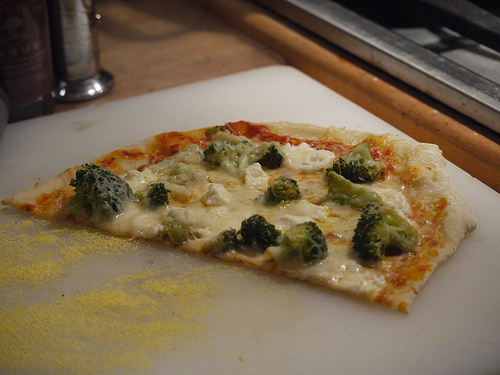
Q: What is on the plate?
A: Yellow seasonings.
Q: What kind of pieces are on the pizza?
A: Broccoli.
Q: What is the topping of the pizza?
A: Cheese.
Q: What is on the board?
A: Pizza.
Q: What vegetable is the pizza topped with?
A: Broccoli.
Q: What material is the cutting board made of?
A: Plastic.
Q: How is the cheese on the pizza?
A: Melted.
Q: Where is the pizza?
A: In a kitchen.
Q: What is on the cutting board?
A: Corn meal.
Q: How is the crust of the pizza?
A: Puffy.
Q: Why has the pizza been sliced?
A: To eat.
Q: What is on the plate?
A: Food.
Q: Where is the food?
A: On the plate.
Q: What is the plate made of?
A: Ceramic.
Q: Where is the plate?
A: On the table.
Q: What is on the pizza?
A: Brocolli.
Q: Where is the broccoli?
A: On the pizza.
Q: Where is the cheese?
A: On the pizza.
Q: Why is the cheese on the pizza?
A: For flavor.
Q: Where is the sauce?
A: On the pizza.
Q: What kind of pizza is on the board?
A: Broccoli and cheese pizza.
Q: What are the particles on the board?
A: Seasoning on the white board.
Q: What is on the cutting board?
A: A piece of pizza on a cutting board.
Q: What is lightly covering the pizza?
A: The sauce was lightly covering the pizza.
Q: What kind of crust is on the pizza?
A: It is a thin crust pizza.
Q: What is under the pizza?
A: There is a cutting board under the pizza.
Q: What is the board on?
A: A table.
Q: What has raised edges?
A: The table has a brown raised edge.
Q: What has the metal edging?
A: A metal edging on the stove.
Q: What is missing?
A: Half a pizza.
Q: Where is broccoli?
A: On the pizza.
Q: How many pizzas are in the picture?
A: One.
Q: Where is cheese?
A: On top of a pizza.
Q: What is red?
A: Tomato sauce.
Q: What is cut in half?
A: A pizza.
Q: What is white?
A: The cheese.